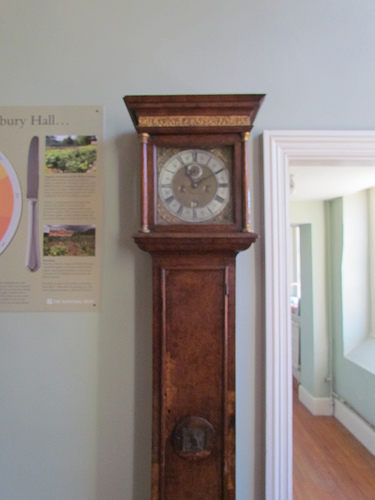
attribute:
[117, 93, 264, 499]
grandfather clock — old, tall, brown, wooden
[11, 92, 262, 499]
wall — white, smooth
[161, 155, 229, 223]
numerals — roman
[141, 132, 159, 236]
dowel — wooden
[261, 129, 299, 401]
molding — white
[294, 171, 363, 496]
hallway — greenish, green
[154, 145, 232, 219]
clockface — ornamental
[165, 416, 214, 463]
object — round wood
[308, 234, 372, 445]
wall — thick, green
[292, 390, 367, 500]
floor boards — hard wood, brown, wooden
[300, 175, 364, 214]
bulb — hanging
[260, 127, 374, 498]
door frame — white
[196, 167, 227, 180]
minute hand — pointing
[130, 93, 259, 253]
frame — brown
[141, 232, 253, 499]
stand — wooden, rusty, straight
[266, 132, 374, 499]
door — opened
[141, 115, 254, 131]
trim — gold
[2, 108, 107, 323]
poster — brown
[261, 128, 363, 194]
door edge — white